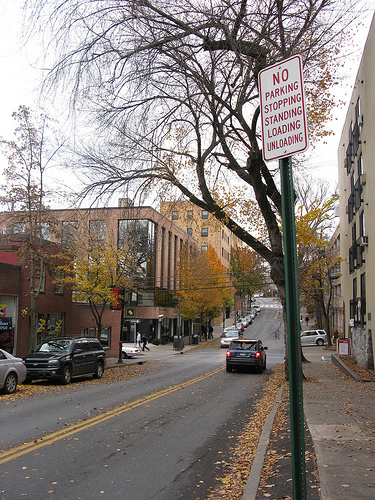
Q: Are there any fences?
A: No, there are no fences.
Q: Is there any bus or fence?
A: No, there are no fences or buses.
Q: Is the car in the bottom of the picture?
A: Yes, the car is in the bottom of the image.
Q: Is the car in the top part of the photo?
A: No, the car is in the bottom of the image.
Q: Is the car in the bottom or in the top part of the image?
A: The car is in the bottom of the image.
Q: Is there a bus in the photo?
A: No, there are no buses.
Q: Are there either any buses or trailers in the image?
A: No, there are no buses or trailers.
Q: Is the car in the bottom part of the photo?
A: Yes, the car is in the bottom of the image.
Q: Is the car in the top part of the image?
A: No, the car is in the bottom of the image.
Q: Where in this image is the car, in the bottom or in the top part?
A: The car is in the bottom of the image.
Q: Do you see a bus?
A: No, there are no buses.